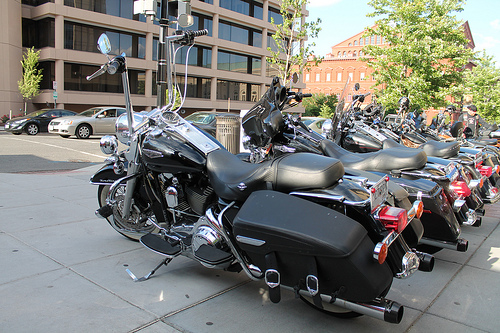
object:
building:
[0, 0, 312, 129]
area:
[0, 124, 143, 164]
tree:
[353, 0, 479, 119]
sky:
[292, 0, 500, 89]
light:
[375, 201, 409, 235]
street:
[1, 102, 497, 331]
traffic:
[148, 22, 201, 111]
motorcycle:
[83, 12, 438, 325]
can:
[210, 111, 247, 157]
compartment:
[225, 187, 397, 303]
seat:
[195, 138, 341, 215]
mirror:
[92, 30, 119, 56]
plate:
[390, 249, 427, 280]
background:
[306, 0, 499, 169]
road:
[0, 112, 144, 176]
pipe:
[272, 281, 404, 325]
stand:
[122, 243, 190, 286]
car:
[43, 104, 141, 139]